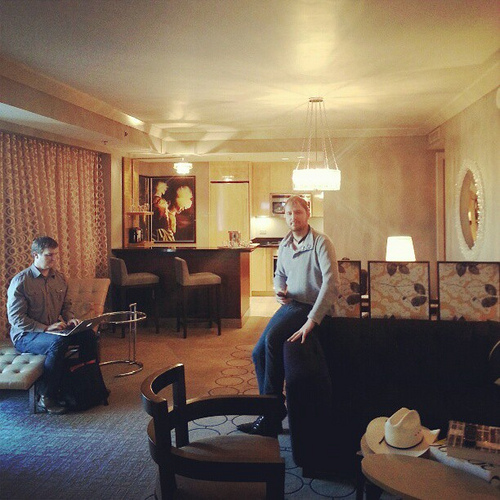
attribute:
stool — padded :
[169, 255, 235, 332]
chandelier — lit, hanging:
[289, 95, 343, 192]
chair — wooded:
[133, 363, 285, 494]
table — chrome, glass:
[96, 303, 146, 378]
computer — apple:
[47, 313, 109, 337]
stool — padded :
[170, 251, 228, 339]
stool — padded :
[107, 251, 167, 312]